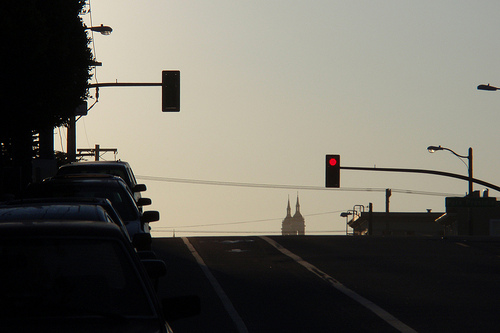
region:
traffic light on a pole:
[319, 146, 349, 190]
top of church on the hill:
[271, 188, 309, 235]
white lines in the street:
[171, 213, 349, 311]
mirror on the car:
[146, 194, 161, 232]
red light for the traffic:
[318, 144, 346, 193]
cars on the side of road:
[33, 153, 146, 299]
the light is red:
[327, 154, 337, 168]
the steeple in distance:
[280, 192, 310, 239]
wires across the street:
[150, 171, 453, 204]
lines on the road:
[184, 225, 416, 330]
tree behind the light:
[2, 2, 180, 120]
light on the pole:
[424, 137, 473, 169]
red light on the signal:
[329, 156, 335, 171]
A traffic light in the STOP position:
[317, 150, 348, 192]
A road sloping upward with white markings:
[178, 233, 343, 303]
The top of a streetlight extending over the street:
[418, 130, 477, 164]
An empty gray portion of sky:
[223, 40, 325, 121]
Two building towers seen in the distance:
[270, 193, 310, 235]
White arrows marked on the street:
[221, 230, 245, 259]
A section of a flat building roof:
[342, 203, 423, 230]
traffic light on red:
[326, 155, 339, 191]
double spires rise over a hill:
[281, 194, 304, 239]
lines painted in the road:
[158, 220, 394, 331]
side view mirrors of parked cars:
[133, 163, 158, 233]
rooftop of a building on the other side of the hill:
[347, 200, 444, 235]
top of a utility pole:
[78, 140, 122, 162]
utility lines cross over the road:
[128, 170, 493, 197]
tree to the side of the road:
[1, 0, 91, 174]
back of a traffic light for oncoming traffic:
[163, 67, 181, 110]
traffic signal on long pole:
[320, 150, 499, 199]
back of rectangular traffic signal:
[156, 67, 187, 119]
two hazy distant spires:
[277, 189, 309, 236]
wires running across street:
[127, 164, 469, 207]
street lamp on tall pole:
[421, 143, 478, 200]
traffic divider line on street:
[251, 224, 421, 331]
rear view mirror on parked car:
[141, 206, 162, 226]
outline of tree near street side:
[2, 1, 100, 147]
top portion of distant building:
[337, 185, 444, 237]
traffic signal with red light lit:
[319, 149, 344, 194]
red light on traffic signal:
[325, 152, 342, 168]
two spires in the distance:
[274, 192, 308, 239]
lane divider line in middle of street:
[259, 228, 404, 331]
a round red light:
[321, 150, 350, 192]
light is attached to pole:
[324, 152, 338, 189]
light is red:
[326, 157, 336, 165]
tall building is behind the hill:
[282, 192, 306, 235]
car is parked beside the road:
[0, 201, 172, 331]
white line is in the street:
[262, 235, 414, 332]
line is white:
[178, 235, 246, 330]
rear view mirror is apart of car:
[143, 207, 158, 220]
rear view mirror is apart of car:
[135, 182, 145, 193]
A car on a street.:
[7, 220, 179, 328]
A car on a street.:
[29, 195, 137, 275]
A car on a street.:
[47, 173, 142, 255]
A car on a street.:
[63, 154, 153, 223]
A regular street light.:
[323, 155, 339, 188]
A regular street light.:
[158, 68, 183, 112]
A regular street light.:
[94, 16, 111, 33]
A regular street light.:
[426, 144, 443, 153]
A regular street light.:
[476, 83, 495, 92]